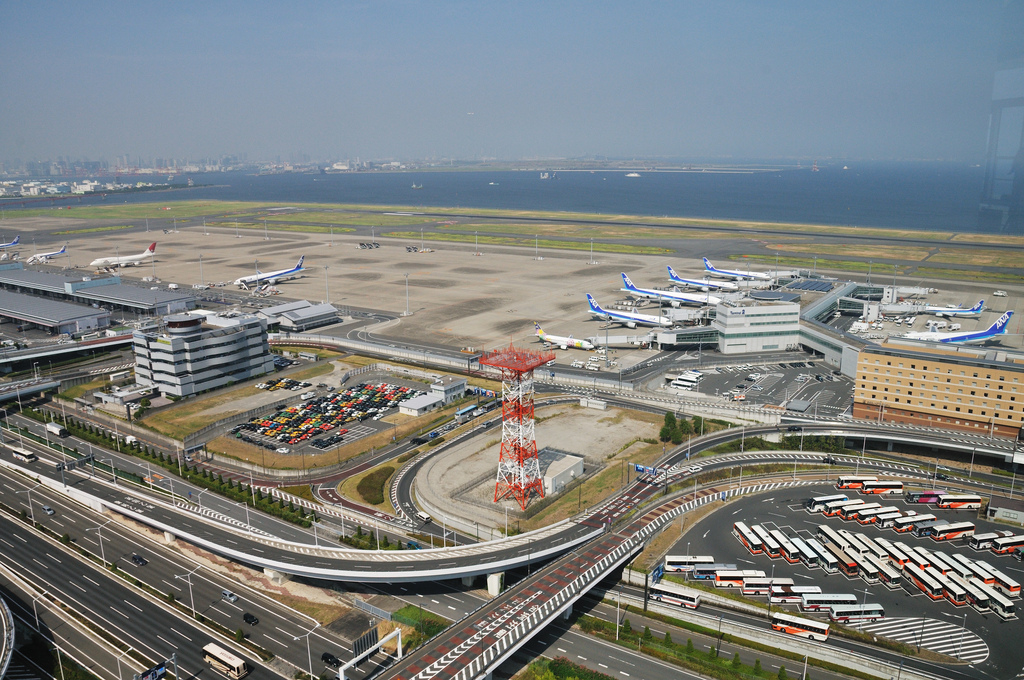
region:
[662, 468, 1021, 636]
Buses in a parking lot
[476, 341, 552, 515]
A tower at an airport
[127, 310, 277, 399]
A building at an airport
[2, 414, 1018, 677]
Roads at an airport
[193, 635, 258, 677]
A bus on a road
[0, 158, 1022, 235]
Water near an airport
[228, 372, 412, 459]
A parking lot full of cars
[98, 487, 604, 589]
A bridge over a road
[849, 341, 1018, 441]
A brown building at an airport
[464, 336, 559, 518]
the tower is white and red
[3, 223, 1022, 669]
planes in an airport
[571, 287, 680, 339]
plane in an airport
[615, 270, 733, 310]
plane in an airport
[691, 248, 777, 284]
plane in an airport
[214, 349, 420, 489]
car in a parking lot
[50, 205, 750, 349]
airplanes parking on an airport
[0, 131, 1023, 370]
water next to an airport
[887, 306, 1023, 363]
plane in an airport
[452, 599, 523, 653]
a street that is grey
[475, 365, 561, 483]
a red and white tower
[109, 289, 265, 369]
a large white building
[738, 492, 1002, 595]
a bunch of white buses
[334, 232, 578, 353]
a large grey parking lot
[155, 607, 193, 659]
white lines on the road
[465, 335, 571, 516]
orange and white metal tower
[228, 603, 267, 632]
car on highway driving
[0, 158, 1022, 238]
blue body of water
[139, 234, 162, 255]
red tail of white airplane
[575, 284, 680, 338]
white and blue airplane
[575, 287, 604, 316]
blue tail of airplane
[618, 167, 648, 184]
white boat in water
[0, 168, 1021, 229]
body of water next to airport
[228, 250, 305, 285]
blue and white plane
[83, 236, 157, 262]
white plane with red tail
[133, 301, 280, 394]
building is large and white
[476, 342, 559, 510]
red and white metal tower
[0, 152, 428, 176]
city skyline across water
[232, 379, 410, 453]
the cars are parked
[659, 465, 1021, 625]
the buses are parked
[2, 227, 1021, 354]
the airplanes are parked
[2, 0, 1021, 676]
the blue sky above the water and land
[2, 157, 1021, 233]
the large body of water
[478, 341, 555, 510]
the tower is red and white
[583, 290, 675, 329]
the airplane is blue and white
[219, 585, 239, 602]
the car is silver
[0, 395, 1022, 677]
the vehicles driving on the road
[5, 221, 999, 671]
highway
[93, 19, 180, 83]
white clouds in blue sky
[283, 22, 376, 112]
white clouds in blue sky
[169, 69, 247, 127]
white clouds in blue sky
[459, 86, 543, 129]
white clouds in blue sky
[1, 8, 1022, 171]
The sky is blue in color.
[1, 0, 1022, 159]
The sky is clear.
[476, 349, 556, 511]
The red and white tower is made from steel.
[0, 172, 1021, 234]
The water is blue in color.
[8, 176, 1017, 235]
The water is calm.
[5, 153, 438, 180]
The buildings are in the background.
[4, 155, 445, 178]
The buildings in the background are out of focus.